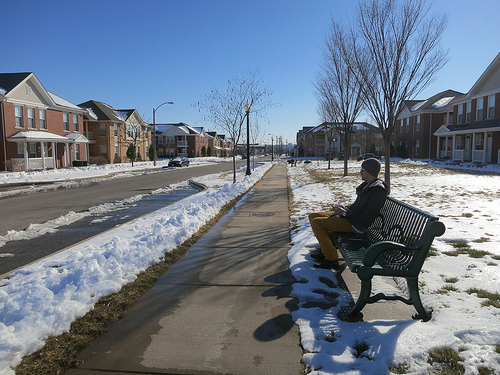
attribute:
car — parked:
[165, 153, 193, 168]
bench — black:
[328, 185, 445, 324]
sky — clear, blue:
[2, 1, 498, 150]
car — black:
[166, 148, 193, 175]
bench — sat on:
[312, 172, 452, 314]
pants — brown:
[299, 189, 367, 259]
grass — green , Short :
[16, 184, 256, 372]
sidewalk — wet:
[73, 159, 306, 371]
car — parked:
[134, 143, 209, 180]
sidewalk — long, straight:
[200, 145, 307, 325]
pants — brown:
[309, 211, 356, 260]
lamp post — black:
[233, 76, 274, 233]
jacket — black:
[348, 180, 391, 227]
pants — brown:
[308, 207, 363, 264]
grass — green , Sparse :
[416, 328, 472, 373]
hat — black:
[360, 159, 380, 173]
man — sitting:
[298, 154, 387, 272]